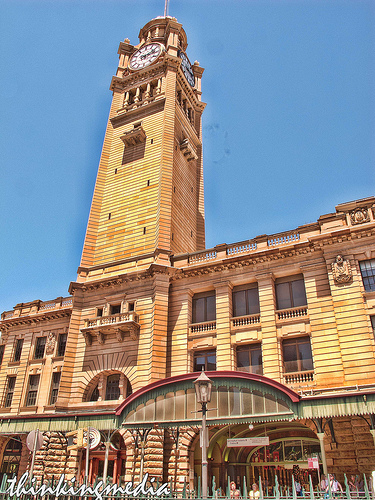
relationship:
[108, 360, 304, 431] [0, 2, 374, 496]
archway on building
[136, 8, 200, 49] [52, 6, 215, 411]
roof over tower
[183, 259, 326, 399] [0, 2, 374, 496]
windows are on building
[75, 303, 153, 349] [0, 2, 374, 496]
balcony on building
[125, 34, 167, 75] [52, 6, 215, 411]
clock on tower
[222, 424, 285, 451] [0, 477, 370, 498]
sign above ground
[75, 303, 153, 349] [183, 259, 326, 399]
balcony next to windows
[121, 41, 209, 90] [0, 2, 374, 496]
two clocks are on building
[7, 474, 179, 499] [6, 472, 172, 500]
signature of signature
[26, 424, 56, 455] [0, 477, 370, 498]
back of sign on ground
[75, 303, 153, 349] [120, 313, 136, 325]
balcony has rails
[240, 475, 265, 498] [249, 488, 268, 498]
person wears white shirt